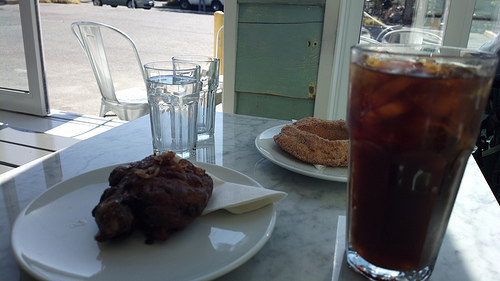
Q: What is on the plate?
A: Meat.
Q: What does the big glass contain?
A: Dark soda.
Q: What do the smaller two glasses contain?
A: Water.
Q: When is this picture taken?
A: During daytime.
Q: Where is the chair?
A: Outside the snack bar.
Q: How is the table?
A: The table has grey granite top.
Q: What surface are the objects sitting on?
A: Marble.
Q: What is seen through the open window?
A: White chair.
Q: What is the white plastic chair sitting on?
A: Cement pavement.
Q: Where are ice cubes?
A: In the brown drink.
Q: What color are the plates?
A: White.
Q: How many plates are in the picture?
A: Two.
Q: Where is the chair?
A: Outside the door.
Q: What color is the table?
A: Gray.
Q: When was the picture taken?
A: During the day.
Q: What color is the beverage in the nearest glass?
A: Brown.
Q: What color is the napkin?
A: White.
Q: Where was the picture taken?
A: In a cafe.